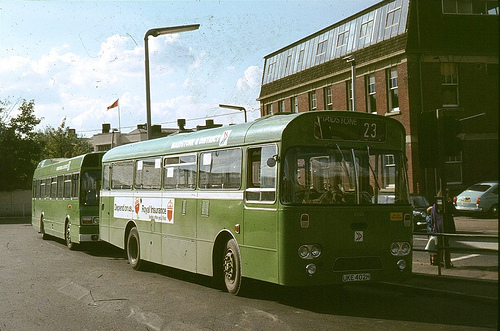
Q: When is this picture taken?
A: Daytime.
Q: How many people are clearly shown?
A: None.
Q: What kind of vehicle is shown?
A: A bus.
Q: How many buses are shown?
A: Two.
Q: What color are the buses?
A: Green.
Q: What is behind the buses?
A: A building.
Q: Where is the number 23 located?
A: Above the windshield of the first bus.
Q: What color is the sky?
A: Blue.